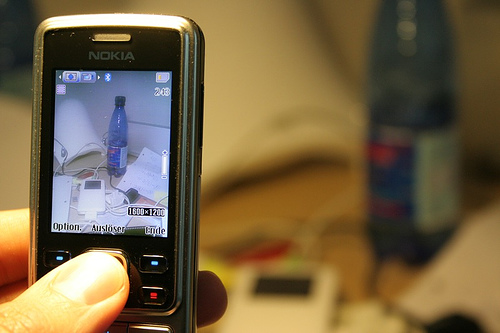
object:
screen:
[52, 71, 172, 236]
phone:
[28, 11, 210, 333]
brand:
[89, 52, 137, 62]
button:
[137, 254, 169, 274]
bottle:
[365, 0, 468, 270]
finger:
[48, 252, 128, 307]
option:
[51, 222, 165, 234]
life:
[154, 71, 172, 85]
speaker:
[91, 32, 135, 43]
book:
[204, 230, 299, 262]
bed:
[197, 126, 500, 333]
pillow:
[1, 29, 32, 55]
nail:
[51, 252, 125, 306]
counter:
[193, 104, 361, 215]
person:
[0, 206, 130, 333]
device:
[26, 14, 204, 333]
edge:
[170, 16, 210, 44]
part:
[368, 0, 463, 267]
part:
[123, 93, 152, 123]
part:
[142, 287, 165, 305]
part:
[299, 184, 329, 191]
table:
[288, 177, 303, 187]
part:
[152, 71, 175, 97]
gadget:
[104, 94, 130, 176]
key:
[43, 248, 71, 268]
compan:
[88, 51, 151, 66]